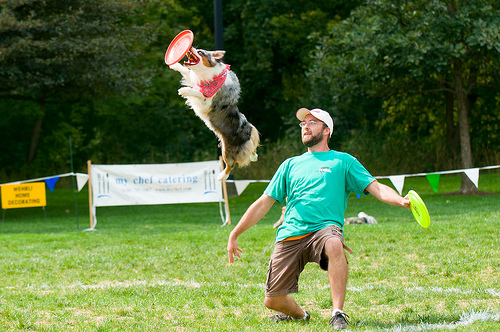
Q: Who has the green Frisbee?
A: The man.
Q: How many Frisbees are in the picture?
A: Two.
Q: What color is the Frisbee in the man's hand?
A: Green.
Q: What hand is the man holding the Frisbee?
A: Left.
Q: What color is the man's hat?
A: White.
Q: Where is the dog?
A: In the air.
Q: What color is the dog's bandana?
A: Red.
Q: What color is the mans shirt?
A: Green.